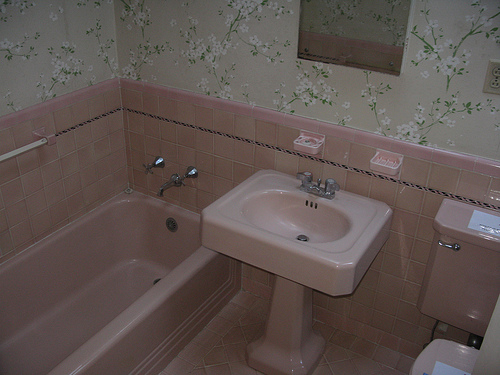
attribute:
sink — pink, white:
[202, 168, 391, 373]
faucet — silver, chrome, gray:
[296, 170, 337, 197]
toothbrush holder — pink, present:
[368, 147, 402, 173]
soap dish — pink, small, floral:
[292, 130, 331, 156]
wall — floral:
[119, 2, 498, 369]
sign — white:
[469, 206, 500, 239]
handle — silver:
[435, 237, 463, 254]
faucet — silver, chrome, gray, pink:
[141, 157, 202, 198]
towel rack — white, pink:
[1, 137, 63, 165]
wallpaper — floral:
[3, 2, 498, 177]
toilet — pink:
[408, 193, 499, 375]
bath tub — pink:
[1, 185, 247, 374]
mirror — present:
[296, 3, 415, 78]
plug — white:
[124, 182, 133, 193]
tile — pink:
[2, 78, 498, 335]